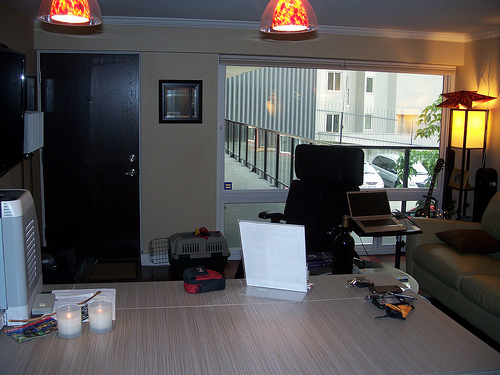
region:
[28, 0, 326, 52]
Two small lights hanging from the ceiling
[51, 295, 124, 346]
Two small white candles on the table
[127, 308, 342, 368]
A wooden table beneath the candles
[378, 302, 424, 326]
A small orange object on the wooden table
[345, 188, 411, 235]
A small grey laptop on the side table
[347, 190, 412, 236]
The grey laptop is opened, but not on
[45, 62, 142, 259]
A plain black door on the wall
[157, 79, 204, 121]
A small mirror hanging on the wall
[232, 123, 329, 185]
A small black fence outside of the window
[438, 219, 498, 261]
A small brown throwpillow on the couch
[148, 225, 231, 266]
pet carrier on floor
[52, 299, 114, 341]
two lit candles on counter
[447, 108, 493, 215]
floor lamp in corner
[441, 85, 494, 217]
red star on floor lamp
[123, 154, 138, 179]
door knob and lock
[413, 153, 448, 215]
neck of guitar by window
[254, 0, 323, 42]
pendulum light fixture above counter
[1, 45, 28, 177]
TV mounted on wall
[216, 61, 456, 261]
big picture window to see out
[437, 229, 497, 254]
throw pillow on couch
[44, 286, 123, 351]
two candles that are lit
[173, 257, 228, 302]
a red and black bag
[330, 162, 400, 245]
a silver laptop that is open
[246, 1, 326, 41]
a red and orange light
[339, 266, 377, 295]
a set of car keys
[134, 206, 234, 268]
a pet cage that is open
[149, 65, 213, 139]
a mirror on the wall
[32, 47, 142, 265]
a black door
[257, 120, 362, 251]
a black office chair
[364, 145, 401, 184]
a blue mini van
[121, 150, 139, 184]
Silver handle for door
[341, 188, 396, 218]
open Laptop computer screen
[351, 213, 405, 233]
Open laptop computer keyboard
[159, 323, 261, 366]
Shiny Beige tile floor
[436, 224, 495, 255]
Dark brown couch pillow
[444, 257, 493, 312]
Part of light brown couch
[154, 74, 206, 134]
Small picture frame on wall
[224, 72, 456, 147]
Part of picture window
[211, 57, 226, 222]
Part of picture window frame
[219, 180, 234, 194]
Alarm system sign on window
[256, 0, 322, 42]
clear plastic covered orange and yellow light fixture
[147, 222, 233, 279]
small animal carrier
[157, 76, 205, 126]
dark framed mirror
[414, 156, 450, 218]
guitar standing on end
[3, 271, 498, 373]
blond wood table surface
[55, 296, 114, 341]
two candles in clear candle holders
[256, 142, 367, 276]
leather reclining chair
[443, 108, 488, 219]
amber lit floor lamp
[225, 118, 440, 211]
see-through metal fencing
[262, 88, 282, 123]
reflection of ceiling light in window